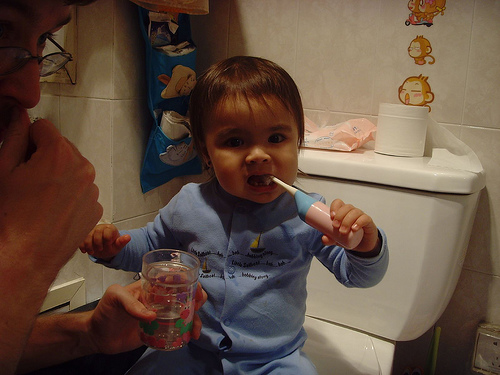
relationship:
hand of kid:
[84, 215, 124, 256] [70, 55, 390, 369]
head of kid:
[193, 77, 343, 200] [121, 46, 401, 366]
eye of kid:
[211, 124, 254, 154] [134, 59, 392, 359]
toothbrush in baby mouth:
[260, 169, 373, 249] [240, 167, 280, 190]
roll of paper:
[342, 51, 466, 181] [363, 75, 463, 183]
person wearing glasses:
[1, 1, 228, 372] [1, 29, 77, 83]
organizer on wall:
[141, 16, 201, 196] [114, 19, 200, 293]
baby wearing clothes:
[77, 53, 390, 374] [88, 175, 389, 372]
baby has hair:
[77, 53, 390, 374] [185, 52, 307, 171]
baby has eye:
[77, 53, 390, 374] [265, 132, 289, 148]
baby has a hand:
[77, 53, 390, 374] [308, 192, 398, 261]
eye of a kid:
[262, 122, 294, 152] [127, 51, 417, 357]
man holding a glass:
[2, 11, 99, 187] [124, 226, 201, 349]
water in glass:
[151, 295, 186, 337] [129, 238, 216, 358]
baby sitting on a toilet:
[77, 53, 390, 374] [213, 93, 443, 370]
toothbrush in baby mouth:
[260, 169, 403, 278] [238, 163, 287, 198]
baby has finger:
[77, 53, 390, 374] [339, 204, 359, 237]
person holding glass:
[83, 59, 387, 373] [137, 243, 198, 343]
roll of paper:
[365, 96, 431, 159] [385, 109, 423, 147]